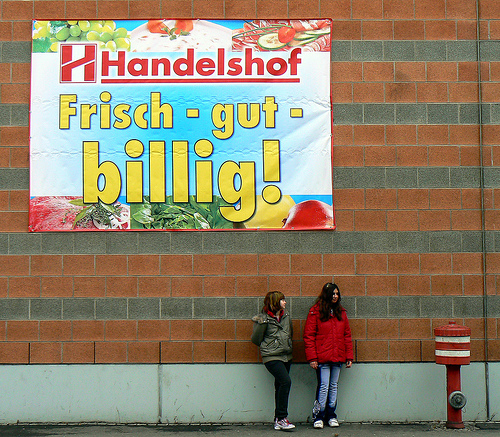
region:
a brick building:
[0, 0, 499, 425]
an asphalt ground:
[0, 421, 499, 435]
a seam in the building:
[475, 0, 490, 421]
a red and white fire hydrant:
[432, 320, 472, 428]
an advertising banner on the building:
[26, 17, 336, 232]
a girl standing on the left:
[250, 290, 295, 430]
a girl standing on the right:
[302, 281, 353, 428]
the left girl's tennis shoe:
[272, 415, 292, 427]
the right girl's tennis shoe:
[312, 419, 322, 426]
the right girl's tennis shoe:
[328, 416, 338, 426]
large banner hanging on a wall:
[28, 18, 336, 232]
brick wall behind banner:
[0, 1, 499, 423]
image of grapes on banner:
[34, 20, 130, 55]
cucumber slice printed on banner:
[258, 33, 287, 48]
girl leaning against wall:
[251, 290, 301, 429]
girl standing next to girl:
[302, 278, 357, 426]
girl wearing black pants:
[265, 358, 294, 419]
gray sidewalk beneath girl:
[0, 421, 499, 435]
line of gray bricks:
[1, 294, 264, 321]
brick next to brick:
[93, 254, 128, 276]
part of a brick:
[415, 210, 435, 228]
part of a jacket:
[323, 330, 330, 332]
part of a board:
[111, 209, 120, 219]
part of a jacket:
[266, 337, 271, 352]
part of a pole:
[446, 353, 451, 367]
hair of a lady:
[321, 286, 328, 301]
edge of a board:
[36, 210, 44, 222]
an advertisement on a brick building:
[17, 17, 336, 234]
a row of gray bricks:
[0, 232, 499, 252]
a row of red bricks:
[1, 252, 498, 276]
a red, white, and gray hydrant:
[433, 319, 470, 423]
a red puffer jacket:
[303, 302, 351, 359]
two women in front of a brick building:
[252, 282, 355, 428]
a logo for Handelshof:
[57, 43, 95, 82]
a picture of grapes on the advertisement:
[27, 15, 124, 47]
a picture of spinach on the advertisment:
[125, 197, 230, 228]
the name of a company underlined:
[97, 48, 304, 88]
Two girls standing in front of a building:
[241, 258, 378, 427]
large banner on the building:
[0, 17, 360, 242]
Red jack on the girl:
[290, 297, 368, 365]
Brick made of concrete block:
[0, 13, 497, 387]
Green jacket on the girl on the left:
[227, 298, 299, 370]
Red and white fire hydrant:
[425, 310, 480, 429]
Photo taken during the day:
[21, 7, 488, 425]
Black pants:
[260, 347, 295, 422]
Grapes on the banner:
[25, 13, 147, 60]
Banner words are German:
[22, 23, 344, 233]